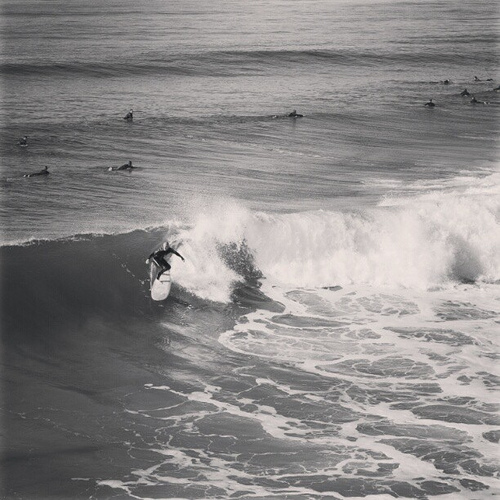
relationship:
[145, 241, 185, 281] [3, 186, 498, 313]
man surfing on wave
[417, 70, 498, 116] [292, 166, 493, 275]
people surf on wave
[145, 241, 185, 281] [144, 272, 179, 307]
man on a surfboard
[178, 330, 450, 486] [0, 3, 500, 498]
ripples in water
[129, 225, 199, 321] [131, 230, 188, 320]
man in a wetsuit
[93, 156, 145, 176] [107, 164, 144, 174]
person laying on a surfboard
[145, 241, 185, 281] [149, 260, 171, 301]
man paddling on a surfboard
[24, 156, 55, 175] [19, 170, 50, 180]
person laying on a surfboard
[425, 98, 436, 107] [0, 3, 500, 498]
people swimming in water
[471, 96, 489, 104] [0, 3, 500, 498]
person swimming in water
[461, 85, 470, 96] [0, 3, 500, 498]
person swimming swimming in water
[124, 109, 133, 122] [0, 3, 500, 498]
person swimming in water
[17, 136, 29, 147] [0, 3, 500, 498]
person swimming in water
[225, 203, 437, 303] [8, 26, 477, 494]
waves in photo